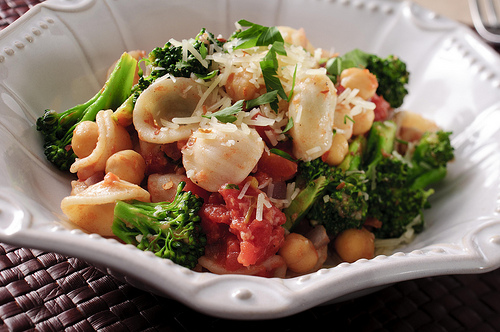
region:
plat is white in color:
[20, 36, 335, 326]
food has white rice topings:
[156, 11, 347, 166]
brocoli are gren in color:
[106, 201, 211, 266]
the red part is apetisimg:
[206, 192, 287, 248]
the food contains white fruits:
[140, 80, 265, 168]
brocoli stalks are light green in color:
[82, 63, 162, 113]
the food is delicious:
[121, 40, 441, 253]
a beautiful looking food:
[62, 40, 444, 262]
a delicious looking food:
[67, 13, 461, 262]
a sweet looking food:
[40, 25, 382, 227]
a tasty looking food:
[50, 13, 402, 220]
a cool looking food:
[45, 28, 445, 250]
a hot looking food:
[46, 23, 405, 242]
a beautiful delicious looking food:
[68, 18, 407, 222]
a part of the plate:
[221, 277, 280, 312]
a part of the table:
[4, 258, 132, 320]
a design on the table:
[94, 260, 334, 324]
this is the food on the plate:
[89, 48, 412, 243]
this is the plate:
[439, 195, 493, 254]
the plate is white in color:
[435, 35, 483, 94]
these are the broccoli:
[320, 160, 412, 216]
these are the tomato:
[214, 185, 276, 257]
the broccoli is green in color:
[142, 198, 195, 248]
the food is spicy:
[91, 23, 356, 225]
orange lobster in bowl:
[138, 63, 349, 182]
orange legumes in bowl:
[32, 107, 140, 167]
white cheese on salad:
[182, 43, 335, 145]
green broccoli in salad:
[30, 39, 465, 253]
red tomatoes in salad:
[192, 192, 287, 274]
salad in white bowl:
[27, 54, 449, 266]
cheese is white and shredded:
[147, 22, 308, 197]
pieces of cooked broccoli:
[55, 51, 130, 164]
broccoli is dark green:
[110, 182, 202, 272]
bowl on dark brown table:
[42, 13, 481, 329]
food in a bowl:
[46, 22, 488, 300]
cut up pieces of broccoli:
[31, 35, 223, 263]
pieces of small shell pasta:
[41, 77, 232, 228]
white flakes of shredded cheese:
[161, 20, 338, 172]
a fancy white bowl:
[6, 7, 494, 326]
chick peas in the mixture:
[281, 225, 397, 272]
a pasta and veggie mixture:
[76, 19, 461, 256]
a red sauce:
[203, 169, 310, 269]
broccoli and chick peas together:
[53, 38, 487, 258]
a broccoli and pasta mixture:
[58, 25, 456, 242]